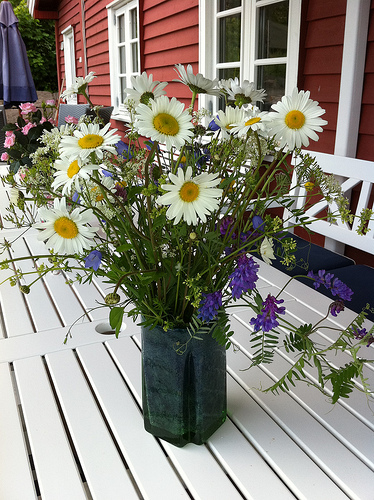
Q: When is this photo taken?
A: Daytime.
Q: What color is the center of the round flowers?
A: Yellow.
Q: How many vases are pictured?
A: One.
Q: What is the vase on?
A: Table.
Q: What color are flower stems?
A: Green.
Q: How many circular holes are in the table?
A: One.